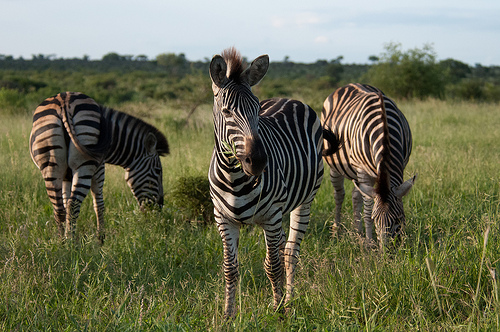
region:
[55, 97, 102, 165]
The tail of the zebra on the left.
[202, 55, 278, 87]
The ears of the zebra in the middle.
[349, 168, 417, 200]
The ears of the zebra on the right.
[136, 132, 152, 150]
The ear of the zebra on the left.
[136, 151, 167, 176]
The eye of the zebra on the left.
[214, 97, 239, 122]
The eye of the zebra in the middle.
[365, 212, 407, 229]
The eyes of the zebra on the right.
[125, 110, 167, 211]
The head of the zebra on the left.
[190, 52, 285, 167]
The head of the zebra in the middle.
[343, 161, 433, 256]
The head of the zebra on the right.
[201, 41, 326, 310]
A black and white striped zebra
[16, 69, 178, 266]
The rear view of a zebra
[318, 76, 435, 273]
A zebra eating grass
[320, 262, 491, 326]
Tall grass in a field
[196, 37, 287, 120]
Two zebra ears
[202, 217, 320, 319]
Three zebra legs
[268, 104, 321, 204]
Stripes on the side of a zebra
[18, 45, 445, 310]
Three zebras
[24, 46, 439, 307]
A small herd of zebras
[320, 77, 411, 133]
The back of a zebra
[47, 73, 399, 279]
Three zebras in the field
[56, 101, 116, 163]
The zebra tail is curved.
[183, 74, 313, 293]
The zebra is black and white.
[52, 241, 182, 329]
The green grass is tall.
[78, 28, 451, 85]
Green trees in the background.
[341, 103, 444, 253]
The zebra is eating grass.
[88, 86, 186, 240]
The zebra is eating.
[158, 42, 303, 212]
The zebra is looking at something.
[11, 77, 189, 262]
The zebra is standing in the tall grass.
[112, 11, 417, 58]
The blue sky is clear.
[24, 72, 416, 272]
there are three zebras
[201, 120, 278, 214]
a piece of grass in the mouth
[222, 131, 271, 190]
the nose is black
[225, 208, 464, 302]
the grass is high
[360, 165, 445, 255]
the zebra is grazing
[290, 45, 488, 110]
the trees are bushy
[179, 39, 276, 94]
the ears are standing up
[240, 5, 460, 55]
clouds are in the sky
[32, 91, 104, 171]
the tail is moving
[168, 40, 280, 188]
the zebra is looking at the camera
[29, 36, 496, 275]
the zebra has stripes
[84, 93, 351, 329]
the zebra has stripes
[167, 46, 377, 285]
the zebra has stripes